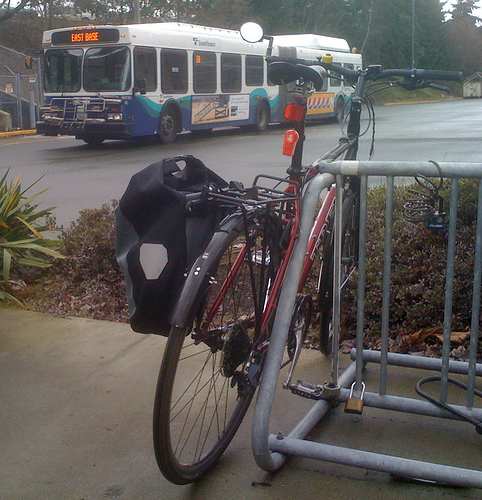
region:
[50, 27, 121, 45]
sign on a bus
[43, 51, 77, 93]
window on a bus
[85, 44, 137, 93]
window on a bus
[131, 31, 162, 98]
window on a bus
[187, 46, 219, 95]
window on a bus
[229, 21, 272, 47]
mirror on a bike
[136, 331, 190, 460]
tire on a bike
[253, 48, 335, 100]
seat on a bike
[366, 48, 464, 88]
handle on a bike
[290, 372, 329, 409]
peddle on a bike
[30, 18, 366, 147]
Very large passenger bus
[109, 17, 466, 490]
Black and red bike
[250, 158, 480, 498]
Grey bike rack with a bike leaning on it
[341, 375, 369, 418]
Gold padlock attached to the bike rack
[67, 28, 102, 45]
Orange east base sign on the bus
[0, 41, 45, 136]
Chain link fence to the left of the bus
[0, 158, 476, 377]
Area of shrubs behind the bike rack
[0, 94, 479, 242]
Paved area the bus is sitting on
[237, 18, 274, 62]
Rearview mirror on the bike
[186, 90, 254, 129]
White advertising sign on the bus with a pic on it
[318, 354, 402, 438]
a lock on bars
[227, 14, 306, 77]
a rear view mirror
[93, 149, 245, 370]
a bag on the bike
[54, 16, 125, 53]
east base on bus sign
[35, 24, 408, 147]
a long bus at stop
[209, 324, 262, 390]
spokes and gears with chain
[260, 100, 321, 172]
to reflectors in rear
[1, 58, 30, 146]
a fence with a sign on it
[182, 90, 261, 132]
a bus billboard on side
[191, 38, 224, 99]
large windows on the bus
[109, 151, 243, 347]
black and gray vinyl backpack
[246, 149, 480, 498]
gray colored metal bike rack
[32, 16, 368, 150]
extra long public transit bus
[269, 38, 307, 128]
black flexible bus extender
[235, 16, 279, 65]
black rear view mirror for bicycle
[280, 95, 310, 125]
red reflector for use on bicycle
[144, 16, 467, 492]
red and black mountain bike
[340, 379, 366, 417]
brass and silver colored paddle lock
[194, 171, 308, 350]
black metal over wheel bike rack with back pack attached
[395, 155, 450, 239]
blue bicycle lock and cable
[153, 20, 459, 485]
a bicycle chained to a rack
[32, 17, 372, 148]
a blue and white city bus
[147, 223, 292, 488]
the rear wheel of a bicycle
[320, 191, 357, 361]
the front wheel of a bicycle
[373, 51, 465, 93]
the handlebar of a bicycle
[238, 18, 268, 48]
a mirror on a bicycle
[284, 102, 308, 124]
a reflector on a bicycle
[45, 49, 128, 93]
the windshield of a bus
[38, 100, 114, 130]
the bike-rack of a bus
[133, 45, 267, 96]
the windows on a bus